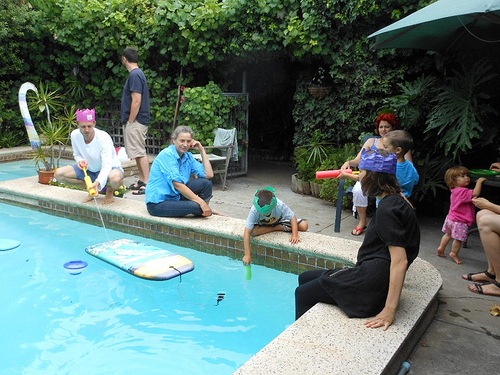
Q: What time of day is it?
A: Daytime.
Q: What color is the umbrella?
A: Green.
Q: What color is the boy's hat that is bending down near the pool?
A: Green.